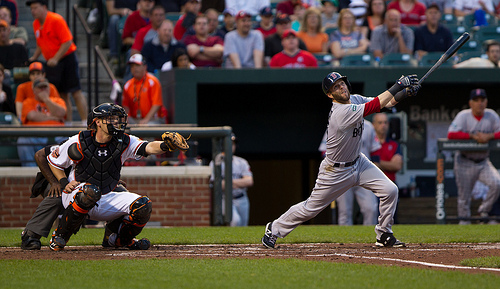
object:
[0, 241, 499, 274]
dirt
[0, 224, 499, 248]
grass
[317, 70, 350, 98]
helmet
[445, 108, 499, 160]
shirt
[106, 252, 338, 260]
lines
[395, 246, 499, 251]
lines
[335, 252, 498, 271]
lines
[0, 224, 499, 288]
baseball field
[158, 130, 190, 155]
glove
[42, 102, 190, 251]
catcher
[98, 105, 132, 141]
face plate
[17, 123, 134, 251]
umpire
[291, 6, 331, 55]
woman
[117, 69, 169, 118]
shirts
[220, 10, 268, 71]
man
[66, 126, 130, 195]
protector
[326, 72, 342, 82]
emblem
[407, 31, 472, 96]
baseball bat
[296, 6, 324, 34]
hair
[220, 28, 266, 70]
shirt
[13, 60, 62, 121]
spectators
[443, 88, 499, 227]
man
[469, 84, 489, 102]
cap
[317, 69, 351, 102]
head